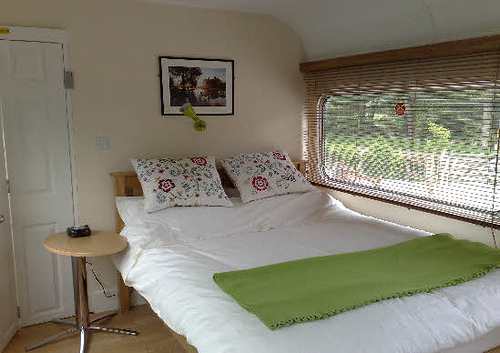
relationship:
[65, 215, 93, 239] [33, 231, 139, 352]
clock on a table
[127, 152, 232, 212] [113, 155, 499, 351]
pillow on bed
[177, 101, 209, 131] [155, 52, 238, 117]
stuffed toy on picture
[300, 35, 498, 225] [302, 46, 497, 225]
blinds are on window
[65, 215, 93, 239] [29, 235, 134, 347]
clock on table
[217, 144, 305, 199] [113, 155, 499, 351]
pillow on bed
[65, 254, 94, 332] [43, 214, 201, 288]
leg of table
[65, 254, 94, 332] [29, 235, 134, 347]
leg of table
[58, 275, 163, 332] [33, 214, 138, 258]
leg of table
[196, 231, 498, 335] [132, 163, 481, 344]
blanket on bed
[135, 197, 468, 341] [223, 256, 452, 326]
comforter on bed